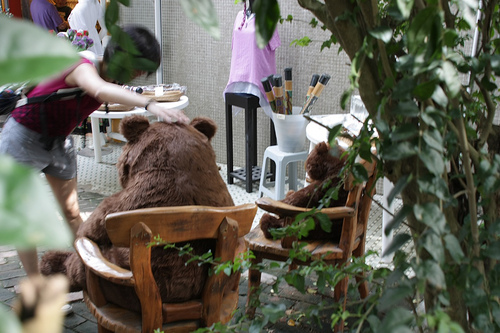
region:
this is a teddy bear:
[74, 104, 251, 296]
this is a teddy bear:
[254, 118, 408, 279]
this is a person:
[2, 19, 176, 330]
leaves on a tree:
[403, 157, 448, 241]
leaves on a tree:
[374, 47, 449, 134]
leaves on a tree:
[369, 267, 406, 331]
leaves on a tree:
[255, 278, 305, 328]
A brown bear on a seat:
[270, 142, 367, 260]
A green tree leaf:
[418, 256, 443, 293]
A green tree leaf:
[380, 135, 422, 170]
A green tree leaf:
[344, 118, 379, 178]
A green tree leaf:
[418, 125, 448, 152]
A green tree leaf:
[397, 93, 414, 119]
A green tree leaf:
[372, 230, 411, 264]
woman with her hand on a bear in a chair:
[7, 28, 250, 331]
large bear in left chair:
[41, 116, 257, 331]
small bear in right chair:
[252, 138, 377, 321]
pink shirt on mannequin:
[230, 1, 282, 97]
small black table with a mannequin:
[223, 0, 277, 192]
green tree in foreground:
[152, 0, 498, 330]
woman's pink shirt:
[11, 58, 114, 135]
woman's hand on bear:
[145, 95, 191, 125]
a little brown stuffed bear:
[260, 136, 345, 241]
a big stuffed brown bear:
[37, 113, 231, 308]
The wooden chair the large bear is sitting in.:
[71, 201, 252, 331]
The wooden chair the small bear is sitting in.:
[257, 142, 372, 314]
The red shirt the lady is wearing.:
[15, 62, 106, 131]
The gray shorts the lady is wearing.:
[7, 123, 77, 180]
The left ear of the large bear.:
[117, 109, 149, 134]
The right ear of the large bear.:
[192, 116, 216, 136]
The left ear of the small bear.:
[318, 138, 325, 150]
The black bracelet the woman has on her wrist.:
[143, 97, 158, 111]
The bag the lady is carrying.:
[0, 75, 27, 110]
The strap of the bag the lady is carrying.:
[25, 78, 89, 100]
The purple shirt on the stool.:
[235, 5, 275, 82]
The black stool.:
[225, 90, 275, 190]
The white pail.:
[265, 95, 305, 150]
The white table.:
[70, 75, 200, 170]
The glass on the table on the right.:
[345, 90, 360, 120]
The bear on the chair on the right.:
[265, 130, 350, 245]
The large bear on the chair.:
[95, 110, 235, 310]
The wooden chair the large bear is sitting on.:
[69, 182, 258, 332]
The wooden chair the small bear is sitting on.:
[250, 143, 373, 303]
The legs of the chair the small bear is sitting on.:
[243, 260, 365, 327]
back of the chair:
[149, 216, 221, 225]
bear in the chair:
[139, 126, 222, 209]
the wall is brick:
[190, 56, 214, 79]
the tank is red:
[29, 99, 57, 122]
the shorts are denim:
[7, 133, 45, 166]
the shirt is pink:
[228, 38, 258, 78]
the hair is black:
[152, 37, 163, 55]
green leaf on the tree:
[415, 175, 451, 201]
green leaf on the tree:
[385, 170, 411, 206]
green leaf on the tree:
[380, 201, 412, 236]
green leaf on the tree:
[412, 195, 438, 235]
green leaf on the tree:
[417, 227, 445, 265]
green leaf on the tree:
[417, 256, 448, 291]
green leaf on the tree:
[327, 120, 343, 146]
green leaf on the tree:
[388, 127, 413, 142]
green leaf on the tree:
[386, 123, 417, 142]